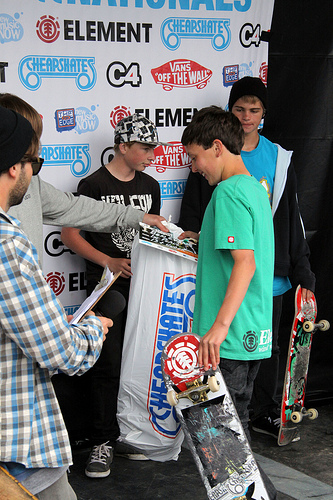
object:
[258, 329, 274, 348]
writing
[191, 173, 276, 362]
green shirt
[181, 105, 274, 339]
person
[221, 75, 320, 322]
person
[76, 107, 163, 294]
person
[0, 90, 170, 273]
person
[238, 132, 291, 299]
shirt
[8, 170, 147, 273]
shirt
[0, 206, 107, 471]
shirt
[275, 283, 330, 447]
skateboard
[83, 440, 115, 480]
sneakers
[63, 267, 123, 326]
clipboard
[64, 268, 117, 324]
paper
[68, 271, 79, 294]
letter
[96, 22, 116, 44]
letter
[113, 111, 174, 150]
hat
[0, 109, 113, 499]
man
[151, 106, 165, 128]
letter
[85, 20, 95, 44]
letter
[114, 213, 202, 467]
shopping bag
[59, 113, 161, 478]
people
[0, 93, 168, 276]
people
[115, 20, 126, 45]
letter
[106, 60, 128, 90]
letter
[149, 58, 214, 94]
advertisement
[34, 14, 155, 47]
advertisement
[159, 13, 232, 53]
advertisement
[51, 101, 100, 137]
advertisement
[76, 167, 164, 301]
tshirt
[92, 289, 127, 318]
microphone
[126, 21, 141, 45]
letter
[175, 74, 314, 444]
boy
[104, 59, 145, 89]
c4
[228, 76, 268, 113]
skull cap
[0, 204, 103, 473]
plaid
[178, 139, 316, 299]
sweatshirt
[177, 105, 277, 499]
boy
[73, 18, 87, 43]
letter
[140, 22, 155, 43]
letter